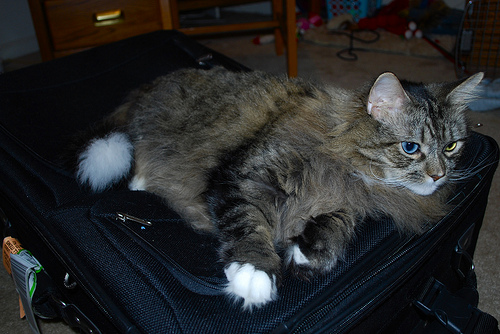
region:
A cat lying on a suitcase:
[155, 85, 457, 197]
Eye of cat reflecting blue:
[400, 141, 419, 152]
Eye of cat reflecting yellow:
[447, 142, 454, 149]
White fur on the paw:
[234, 267, 264, 294]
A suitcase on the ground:
[148, 267, 212, 332]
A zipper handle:
[127, 215, 142, 223]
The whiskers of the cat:
[453, 169, 468, 176]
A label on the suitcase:
[10, 259, 30, 279]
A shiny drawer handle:
[98, 15, 116, 22]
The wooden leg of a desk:
[290, 17, 294, 51]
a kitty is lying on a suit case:
[12, 6, 495, 332]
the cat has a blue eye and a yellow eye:
[347, 61, 493, 213]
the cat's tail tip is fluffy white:
[73, 118, 143, 199]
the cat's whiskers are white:
[333, 148, 490, 214]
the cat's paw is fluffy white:
[219, 255, 276, 313]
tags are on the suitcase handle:
[1, 230, 61, 330]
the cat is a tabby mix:
[80, 55, 483, 312]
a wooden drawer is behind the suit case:
[20, 0, 177, 40]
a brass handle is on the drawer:
[86, 5, 126, 31]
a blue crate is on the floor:
[323, 0, 385, 32]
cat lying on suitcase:
[68, 54, 489, 317]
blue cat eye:
[387, 133, 422, 159]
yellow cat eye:
[441, 133, 463, 157]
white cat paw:
[220, 253, 286, 310]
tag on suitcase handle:
[2, 228, 45, 333]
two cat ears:
[355, 56, 491, 116]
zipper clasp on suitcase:
[112, 204, 159, 232]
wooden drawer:
[42, 3, 168, 52]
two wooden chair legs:
[262, 0, 306, 77]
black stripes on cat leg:
[207, 189, 267, 255]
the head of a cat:
[369, 60, 497, 203]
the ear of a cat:
[351, 68, 418, 137]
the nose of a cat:
[418, 158, 471, 188]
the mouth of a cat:
[399, 152, 454, 221]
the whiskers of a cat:
[383, 158, 498, 203]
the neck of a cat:
[304, 56, 415, 212]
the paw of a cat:
[198, 239, 313, 309]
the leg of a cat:
[198, 131, 297, 288]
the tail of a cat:
[68, 71, 185, 186]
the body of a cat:
[114, 24, 341, 216]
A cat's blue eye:
[398, 138, 420, 153]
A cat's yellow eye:
[446, 141, 454, 151]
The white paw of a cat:
[225, 260, 273, 305]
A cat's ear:
[365, 70, 410, 116]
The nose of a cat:
[425, 158, 447, 180]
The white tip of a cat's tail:
[73, 137, 134, 188]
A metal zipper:
[115, 211, 153, 231]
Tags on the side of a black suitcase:
[2, 236, 49, 330]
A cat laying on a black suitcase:
[77, 65, 480, 308]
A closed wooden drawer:
[35, 0, 173, 41]